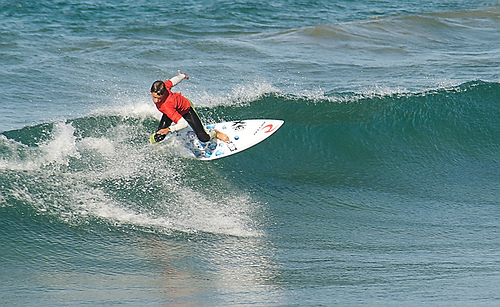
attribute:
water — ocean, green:
[8, 10, 484, 295]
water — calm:
[368, 192, 470, 301]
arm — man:
[151, 106, 183, 142]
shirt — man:
[154, 80, 194, 121]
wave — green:
[324, 118, 429, 159]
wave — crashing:
[2, 75, 482, 237]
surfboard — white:
[158, 115, 284, 162]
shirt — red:
[153, 77, 192, 124]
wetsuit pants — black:
[152, 103, 213, 143]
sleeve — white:
[167, 72, 186, 83]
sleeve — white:
[166, 116, 189, 132]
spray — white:
[3, 60, 458, 240]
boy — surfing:
[145, 67, 231, 145]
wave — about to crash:
[261, 64, 493, 185]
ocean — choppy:
[6, 7, 495, 301]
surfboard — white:
[167, 115, 287, 163]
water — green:
[0, 0, 500, 303]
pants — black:
[156, 107, 216, 147]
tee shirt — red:
[153, 73, 194, 124]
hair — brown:
[148, 77, 172, 100]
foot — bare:
[206, 126, 236, 144]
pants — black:
[151, 103, 213, 147]